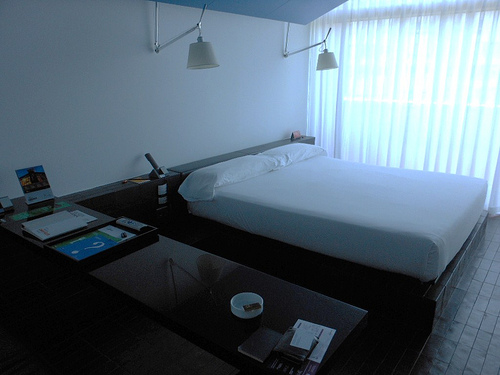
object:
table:
[2, 201, 366, 375]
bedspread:
[176, 142, 487, 278]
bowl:
[231, 292, 264, 318]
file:
[54, 235, 117, 261]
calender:
[15, 166, 55, 205]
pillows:
[263, 143, 326, 169]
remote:
[143, 153, 166, 177]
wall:
[1, 1, 312, 199]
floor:
[1, 214, 499, 374]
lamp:
[185, 37, 217, 71]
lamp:
[316, 46, 339, 71]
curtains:
[308, 1, 353, 152]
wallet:
[273, 328, 320, 364]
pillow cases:
[177, 153, 272, 202]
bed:
[185, 141, 486, 283]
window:
[307, 1, 499, 214]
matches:
[243, 302, 262, 311]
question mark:
[70, 241, 105, 254]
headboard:
[173, 137, 317, 190]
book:
[238, 325, 282, 362]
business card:
[289, 326, 317, 352]